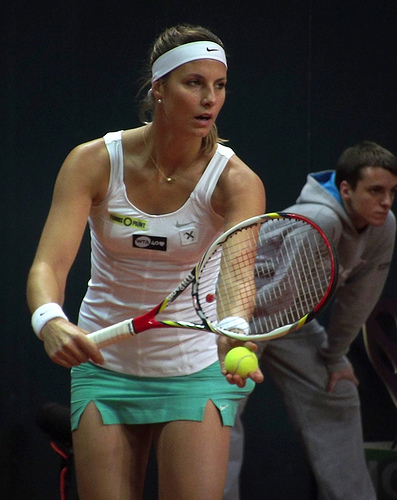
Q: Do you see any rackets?
A: Yes, there is a racket.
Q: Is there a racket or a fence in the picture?
A: Yes, there is a racket.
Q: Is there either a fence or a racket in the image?
A: Yes, there is a racket.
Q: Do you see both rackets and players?
A: Yes, there are both a racket and a player.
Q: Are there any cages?
A: No, there are no cages.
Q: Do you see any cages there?
A: No, there are no cages.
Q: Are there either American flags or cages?
A: No, there are no cages or American flags.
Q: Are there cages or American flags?
A: No, there are no cages or American flags.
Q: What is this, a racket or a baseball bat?
A: This is a racket.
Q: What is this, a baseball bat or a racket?
A: This is a racket.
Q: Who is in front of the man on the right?
A: The player is in front of the man.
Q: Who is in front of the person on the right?
A: The player is in front of the man.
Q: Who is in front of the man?
A: The player is in front of the man.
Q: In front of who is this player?
A: The player is in front of the man.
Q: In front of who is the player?
A: The player is in front of the man.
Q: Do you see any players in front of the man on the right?
A: Yes, there is a player in front of the man.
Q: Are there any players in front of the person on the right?
A: Yes, there is a player in front of the man.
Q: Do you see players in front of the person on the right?
A: Yes, there is a player in front of the man.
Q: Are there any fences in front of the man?
A: No, there is a player in front of the man.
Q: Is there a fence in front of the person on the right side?
A: No, there is a player in front of the man.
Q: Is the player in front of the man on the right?
A: Yes, the player is in front of the man.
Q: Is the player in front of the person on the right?
A: Yes, the player is in front of the man.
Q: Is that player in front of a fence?
A: No, the player is in front of the man.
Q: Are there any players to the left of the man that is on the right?
A: Yes, there is a player to the left of the man.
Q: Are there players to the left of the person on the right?
A: Yes, there is a player to the left of the man.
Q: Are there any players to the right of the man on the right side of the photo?
A: No, the player is to the left of the man.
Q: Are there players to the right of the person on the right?
A: No, the player is to the left of the man.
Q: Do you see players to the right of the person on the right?
A: No, the player is to the left of the man.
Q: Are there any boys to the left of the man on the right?
A: No, there is a player to the left of the man.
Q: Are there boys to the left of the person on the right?
A: No, there is a player to the left of the man.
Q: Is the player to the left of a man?
A: Yes, the player is to the left of a man.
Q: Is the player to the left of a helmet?
A: No, the player is to the left of a man.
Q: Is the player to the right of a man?
A: No, the player is to the left of a man.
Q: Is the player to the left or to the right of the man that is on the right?
A: The player is to the left of the man.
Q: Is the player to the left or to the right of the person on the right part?
A: The player is to the left of the man.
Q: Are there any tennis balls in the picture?
A: Yes, there is a tennis ball.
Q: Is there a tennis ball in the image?
A: Yes, there is a tennis ball.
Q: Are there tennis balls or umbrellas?
A: Yes, there is a tennis ball.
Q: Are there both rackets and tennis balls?
A: Yes, there are both a tennis ball and a racket.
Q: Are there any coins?
A: No, there are no coins.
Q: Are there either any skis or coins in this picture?
A: No, there are no coins or skis.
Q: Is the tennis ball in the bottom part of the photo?
A: Yes, the tennis ball is in the bottom of the image.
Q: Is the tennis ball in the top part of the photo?
A: No, the tennis ball is in the bottom of the image.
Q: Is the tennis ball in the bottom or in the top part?
A: The tennis ball is in the bottom of the image.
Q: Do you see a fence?
A: No, there are no fences.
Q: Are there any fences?
A: No, there are no fences.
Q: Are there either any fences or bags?
A: No, there are no fences or bags.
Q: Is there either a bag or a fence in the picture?
A: No, there are no fences or bags.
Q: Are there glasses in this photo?
A: No, there are no glasses.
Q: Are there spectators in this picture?
A: No, there are no spectators.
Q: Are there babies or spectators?
A: No, there are no spectators or babies.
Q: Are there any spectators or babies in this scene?
A: No, there are no spectators or babies.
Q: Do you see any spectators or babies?
A: No, there are no spectators or babies.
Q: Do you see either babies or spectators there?
A: No, there are no spectators or babies.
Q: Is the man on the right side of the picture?
A: Yes, the man is on the right of the image.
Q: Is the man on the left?
A: No, the man is on the right of the image.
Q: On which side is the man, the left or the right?
A: The man is on the right of the image.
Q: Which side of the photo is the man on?
A: The man is on the right of the image.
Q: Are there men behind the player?
A: Yes, there is a man behind the player.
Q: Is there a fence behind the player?
A: No, there is a man behind the player.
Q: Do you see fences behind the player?
A: No, there is a man behind the player.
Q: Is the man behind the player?
A: Yes, the man is behind the player.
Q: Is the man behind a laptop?
A: No, the man is behind the player.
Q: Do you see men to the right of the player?
A: Yes, there is a man to the right of the player.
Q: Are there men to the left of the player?
A: No, the man is to the right of the player.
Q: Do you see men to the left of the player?
A: No, the man is to the right of the player.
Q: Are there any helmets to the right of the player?
A: No, there is a man to the right of the player.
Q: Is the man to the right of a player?
A: Yes, the man is to the right of a player.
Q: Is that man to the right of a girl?
A: No, the man is to the right of a player.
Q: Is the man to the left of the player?
A: No, the man is to the right of the player.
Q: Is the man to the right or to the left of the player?
A: The man is to the right of the player.